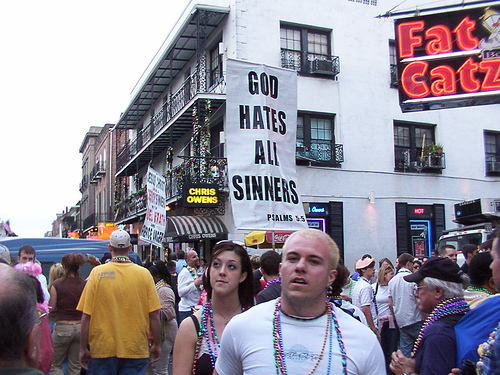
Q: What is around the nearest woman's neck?
A: Beads.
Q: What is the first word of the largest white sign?
A: God.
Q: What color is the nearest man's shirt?
A: White.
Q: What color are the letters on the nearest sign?
A: Red.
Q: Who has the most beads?
A: Man with hat.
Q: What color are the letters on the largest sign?
A: Black.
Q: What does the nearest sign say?
A: Fat Catz.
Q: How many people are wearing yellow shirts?
A: One.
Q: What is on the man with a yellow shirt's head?
A: Hat.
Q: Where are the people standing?
A: Street.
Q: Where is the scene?
A: City intersection.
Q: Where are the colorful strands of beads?
A: Around the man's neck.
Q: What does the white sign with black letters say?
A: God hates all sinners.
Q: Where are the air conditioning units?
A: In the windows.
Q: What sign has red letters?
A: Fat Catz.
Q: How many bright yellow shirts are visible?
A: One.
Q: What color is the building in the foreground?
A: White.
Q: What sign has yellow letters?
A: Chris Owens.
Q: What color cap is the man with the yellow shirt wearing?
A: White.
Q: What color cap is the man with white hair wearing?
A: Black.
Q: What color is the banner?
A: White.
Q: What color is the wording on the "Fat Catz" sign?
A: Red.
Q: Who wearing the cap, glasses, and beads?
A: The man.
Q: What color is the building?
A: Black and white.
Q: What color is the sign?
A: White with black letters.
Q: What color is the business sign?
A: Neon.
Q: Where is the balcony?
A: Building.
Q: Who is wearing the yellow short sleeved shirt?
A: The man.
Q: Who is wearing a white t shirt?
A: The man.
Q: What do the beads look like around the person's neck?
A: Colorful beads.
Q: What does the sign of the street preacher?
A: God Hates All Sinners.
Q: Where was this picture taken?
A: On a busy street.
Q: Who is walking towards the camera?
A: Two people.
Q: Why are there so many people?
A: It is Mardi Gras.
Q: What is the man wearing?
A: Beads.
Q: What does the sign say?
A: God hates all sinners.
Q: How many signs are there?
A: Six.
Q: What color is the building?
A: White.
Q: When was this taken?
A: During the day.